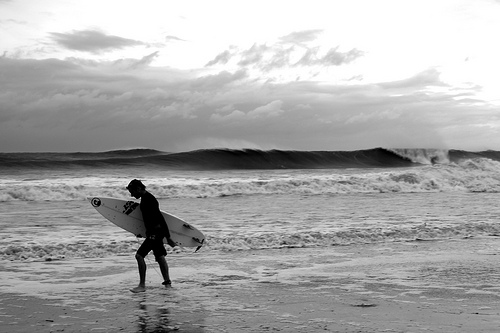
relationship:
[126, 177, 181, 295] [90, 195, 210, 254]
man holding surfboard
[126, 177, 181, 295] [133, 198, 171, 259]
man wearing a wetsuit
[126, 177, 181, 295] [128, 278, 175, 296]
man has wet feet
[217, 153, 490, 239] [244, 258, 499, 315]
waves are coming to shore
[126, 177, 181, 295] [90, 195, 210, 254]
man holding surfing board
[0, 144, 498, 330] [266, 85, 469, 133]
water has mist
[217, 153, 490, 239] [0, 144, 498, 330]
ocean has water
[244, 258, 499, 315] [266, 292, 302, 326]
beach has sand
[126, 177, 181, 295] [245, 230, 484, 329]
surfer on beach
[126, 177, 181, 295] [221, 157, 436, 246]
person getting ready to surf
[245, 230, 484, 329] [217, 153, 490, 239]
beach has waves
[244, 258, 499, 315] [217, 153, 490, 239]
shore has breaking waves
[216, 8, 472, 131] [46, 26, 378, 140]
sky has clouds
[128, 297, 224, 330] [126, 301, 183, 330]
water has reflection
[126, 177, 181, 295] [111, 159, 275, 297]
man finding surfing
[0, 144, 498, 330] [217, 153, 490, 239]
water has waves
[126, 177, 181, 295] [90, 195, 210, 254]
person holding surfboard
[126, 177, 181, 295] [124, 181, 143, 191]
person has on a hat